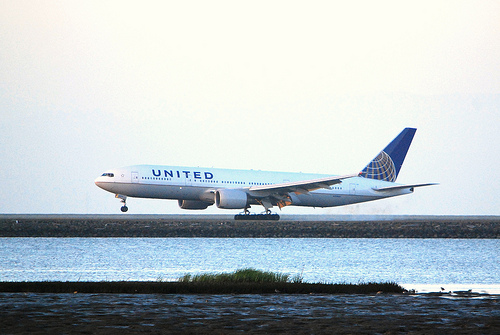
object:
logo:
[368, 151, 412, 178]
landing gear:
[118, 204, 134, 214]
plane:
[93, 123, 455, 231]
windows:
[210, 179, 214, 182]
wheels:
[266, 214, 273, 221]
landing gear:
[234, 214, 240, 220]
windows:
[243, 181, 246, 184]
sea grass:
[158, 263, 311, 290]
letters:
[150, 163, 163, 179]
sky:
[0, 1, 498, 210]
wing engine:
[208, 188, 251, 209]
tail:
[358, 124, 418, 183]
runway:
[2, 202, 499, 223]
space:
[3, 292, 499, 330]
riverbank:
[2, 276, 494, 305]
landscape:
[2, 210, 499, 248]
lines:
[389, 146, 394, 182]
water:
[3, 232, 497, 302]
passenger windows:
[142, 176, 144, 179]